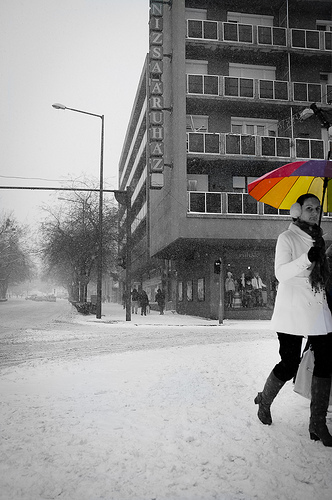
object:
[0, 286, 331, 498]
street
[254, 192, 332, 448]
woman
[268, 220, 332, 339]
coat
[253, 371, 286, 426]
boot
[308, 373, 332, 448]
boot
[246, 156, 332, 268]
umbrella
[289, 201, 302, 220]
ear muff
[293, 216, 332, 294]
scarf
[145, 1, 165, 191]
sign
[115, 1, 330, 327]
building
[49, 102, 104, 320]
street light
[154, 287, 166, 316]
person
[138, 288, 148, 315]
person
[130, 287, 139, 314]
person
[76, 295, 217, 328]
sidewalk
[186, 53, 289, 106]
balcony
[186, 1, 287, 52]
balcony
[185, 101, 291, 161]
balcony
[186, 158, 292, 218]
balcony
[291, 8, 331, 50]
balcony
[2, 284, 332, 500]
snow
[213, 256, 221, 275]
sign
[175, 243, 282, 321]
store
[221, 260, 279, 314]
window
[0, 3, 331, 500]
scene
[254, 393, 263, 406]
heel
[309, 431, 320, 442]
heel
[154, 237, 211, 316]
corner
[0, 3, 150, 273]
sky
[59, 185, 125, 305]
tree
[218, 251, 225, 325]
pole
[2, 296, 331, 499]
ground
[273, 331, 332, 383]
pants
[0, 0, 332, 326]
background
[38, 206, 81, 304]
tree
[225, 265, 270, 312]
mannequins